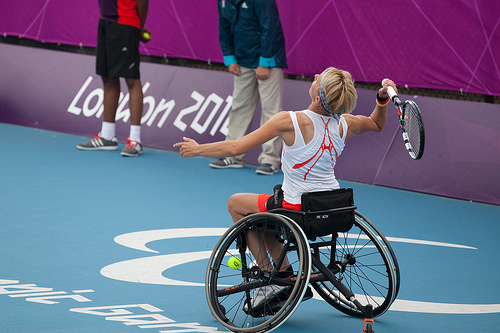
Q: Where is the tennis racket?
A: In the woman's right hand.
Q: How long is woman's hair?
A: Short.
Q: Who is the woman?
A: The tennis player.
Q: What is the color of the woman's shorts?
A: Red.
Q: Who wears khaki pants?
A: A man in the background.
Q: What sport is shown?
A: Tennis.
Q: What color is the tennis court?
A: Blue.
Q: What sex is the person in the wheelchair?
A: Female.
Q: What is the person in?
A: Wheelchair.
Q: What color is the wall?
A: Purple.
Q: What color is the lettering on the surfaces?
A: White.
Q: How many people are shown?
A: Three.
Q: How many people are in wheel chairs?
A: One.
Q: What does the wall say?
A: London 2010.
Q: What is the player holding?
A: Tennis racket.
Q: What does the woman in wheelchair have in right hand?
A: Tennis racket.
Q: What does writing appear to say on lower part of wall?
A: London 2012.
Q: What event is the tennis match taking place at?
A: Special olympics.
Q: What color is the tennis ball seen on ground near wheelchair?
A: Green.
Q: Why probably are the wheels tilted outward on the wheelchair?
A: For faster mobility.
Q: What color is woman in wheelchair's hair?
A: Blonde.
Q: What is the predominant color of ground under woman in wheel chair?
A: Blue.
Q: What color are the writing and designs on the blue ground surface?
A: White.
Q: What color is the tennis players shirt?
A: White with red design.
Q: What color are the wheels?
A: Gray.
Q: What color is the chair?
A: Black.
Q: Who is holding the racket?
A: The tennis player.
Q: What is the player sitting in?
A: A wheelchair.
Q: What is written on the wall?
A: London 2014.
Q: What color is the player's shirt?
A: White and red.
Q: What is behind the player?
A: A water bottle.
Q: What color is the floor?
A: Blue and white.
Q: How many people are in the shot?
A: 3.